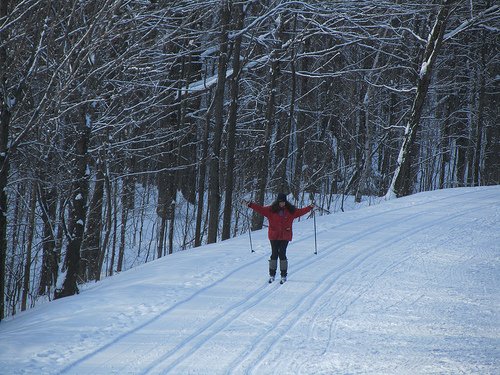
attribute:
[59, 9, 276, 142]
trees — bare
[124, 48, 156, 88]
branches — tree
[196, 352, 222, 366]
white — very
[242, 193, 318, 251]
jacket — red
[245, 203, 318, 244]
jacket — red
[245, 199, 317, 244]
jacket — red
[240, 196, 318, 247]
jacket — red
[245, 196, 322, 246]
jacket — red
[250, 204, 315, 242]
jacket — red winter 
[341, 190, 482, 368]
hill — snow covered 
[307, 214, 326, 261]
pole — ski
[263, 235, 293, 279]
pants — black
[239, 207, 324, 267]
poles — two ski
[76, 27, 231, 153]
branches — bare leafless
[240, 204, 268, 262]
pole — snow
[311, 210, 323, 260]
pole — snow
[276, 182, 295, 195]
hair — long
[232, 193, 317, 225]
arms — outstretched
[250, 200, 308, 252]
coat — red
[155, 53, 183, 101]
branches — brown